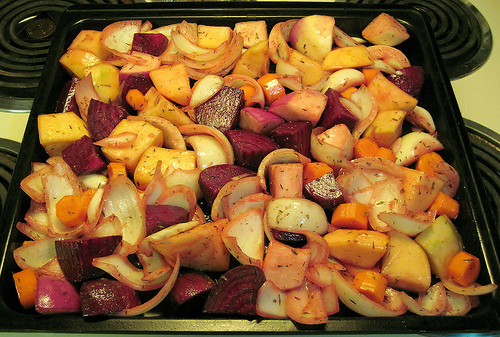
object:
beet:
[131, 33, 170, 57]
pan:
[0, 0, 500, 337]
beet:
[86, 98, 129, 142]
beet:
[195, 85, 245, 136]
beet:
[198, 163, 258, 207]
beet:
[202, 265, 265, 316]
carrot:
[125, 89, 148, 111]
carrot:
[56, 195, 88, 228]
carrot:
[11, 267, 39, 309]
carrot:
[331, 203, 367, 231]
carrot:
[447, 251, 480, 288]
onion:
[263, 241, 312, 291]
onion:
[98, 20, 147, 66]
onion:
[91, 253, 172, 292]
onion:
[188, 74, 224, 108]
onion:
[170, 26, 229, 62]